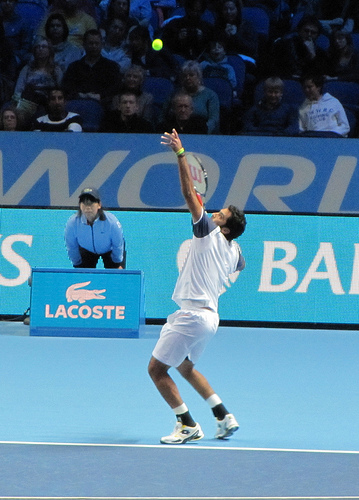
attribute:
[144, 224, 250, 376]
outfit — here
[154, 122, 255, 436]
player — watching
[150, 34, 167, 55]
ball — yellow, served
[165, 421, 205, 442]
shoe — blue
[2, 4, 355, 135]
spectators — watching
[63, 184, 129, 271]
woman — watching, bending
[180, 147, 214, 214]
racket — wilson, held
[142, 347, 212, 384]
knees — bent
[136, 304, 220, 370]
shorts — white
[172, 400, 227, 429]
socks — black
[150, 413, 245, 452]
shoes — white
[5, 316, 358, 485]
court — blue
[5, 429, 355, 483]
line — blue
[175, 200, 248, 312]
shirt — white